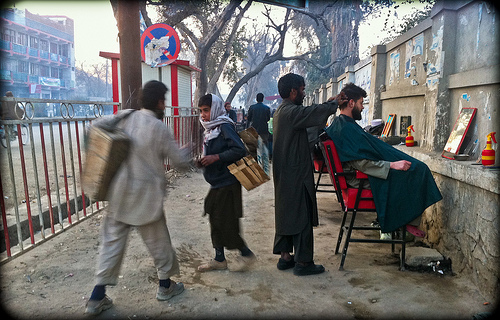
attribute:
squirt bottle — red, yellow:
[474, 130, 491, 164]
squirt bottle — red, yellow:
[403, 120, 415, 145]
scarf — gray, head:
[196, 91, 233, 141]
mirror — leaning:
[445, 109, 475, 151]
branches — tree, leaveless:
[155, 14, 374, 117]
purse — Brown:
[224, 151, 271, 191]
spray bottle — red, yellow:
[403, 122, 415, 149]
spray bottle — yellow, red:
[480, 130, 497, 165]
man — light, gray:
[79, 78, 198, 317]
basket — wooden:
[76, 118, 126, 205]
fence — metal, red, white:
[1, 83, 212, 249]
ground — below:
[181, 257, 496, 318]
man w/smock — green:
[325, 85, 429, 224]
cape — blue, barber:
[324, 112, 443, 234]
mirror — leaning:
[444, 93, 480, 167]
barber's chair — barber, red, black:
[320, 142, 382, 226]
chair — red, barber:
[319, 138, 405, 275]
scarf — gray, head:
[193, 93, 233, 137]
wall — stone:
[391, 0, 499, 300]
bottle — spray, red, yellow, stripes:
[482, 133, 497, 164]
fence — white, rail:
[8, 112, 102, 266]